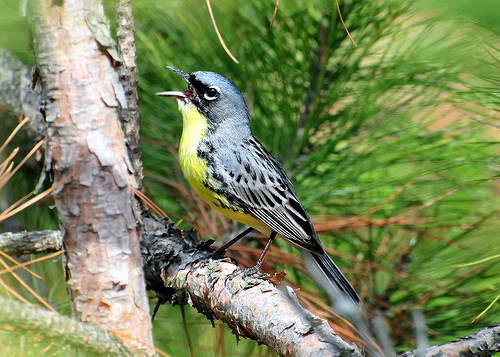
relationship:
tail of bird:
[299, 249, 364, 304] [156, 65, 362, 307]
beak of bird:
[155, 66, 191, 99] [156, 65, 362, 307]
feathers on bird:
[246, 193, 346, 260] [173, 67, 365, 299]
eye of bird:
[194, 74, 235, 114] [156, 65, 362, 307]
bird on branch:
[156, 65, 362, 307] [130, 207, 366, 355]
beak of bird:
[150, 62, 191, 99] [154, 65, 385, 355]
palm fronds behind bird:
[133, 0, 499, 353] [156, 65, 362, 307]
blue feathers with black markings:
[222, 135, 299, 219] [243, 170, 273, 203]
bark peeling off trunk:
[87, 7, 142, 219] [26, 0, 159, 352]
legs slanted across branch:
[190, 225, 278, 282] [142, 214, 498, 355]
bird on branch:
[156, 61, 374, 327] [140, 216, 378, 354]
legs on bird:
[188, 214, 290, 286] [156, 65, 362, 307]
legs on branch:
[188, 214, 290, 286] [130, 207, 366, 355]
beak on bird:
[155, 66, 191, 99] [186, 55, 360, 285]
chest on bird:
[178, 120, 243, 211] [156, 65, 362, 307]